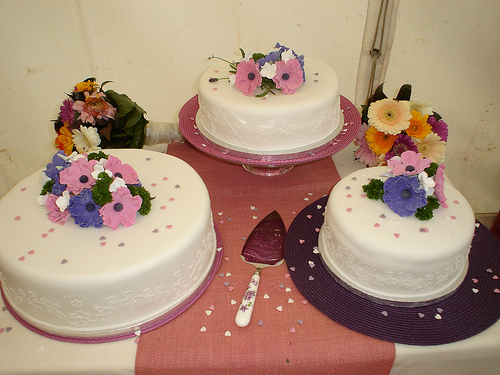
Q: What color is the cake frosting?
A: White.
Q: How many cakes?
A: Three.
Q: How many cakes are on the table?
A: Three.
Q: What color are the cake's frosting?
A: White.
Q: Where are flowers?
A: On the table.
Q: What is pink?
A: Two plates.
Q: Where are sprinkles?
A: On the cakes.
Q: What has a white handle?
A: Spatula.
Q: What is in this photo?
A: Cakes.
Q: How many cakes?
A: Three.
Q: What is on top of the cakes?
A: Icing.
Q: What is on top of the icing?
A: Flowers.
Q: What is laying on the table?
A: Knife to cut cake.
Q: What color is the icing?
A: White.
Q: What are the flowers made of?
A: Icing.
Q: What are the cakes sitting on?
A: A table.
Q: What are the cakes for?
A: Birthday.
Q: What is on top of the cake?
A: Many little flowers.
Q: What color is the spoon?
A: Silver and white.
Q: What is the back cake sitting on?
A: A cake stand.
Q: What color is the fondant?
A: White.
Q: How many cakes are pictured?
A: 3.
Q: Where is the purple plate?
A: Right.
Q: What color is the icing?
A: White.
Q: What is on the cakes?
A: Flowers.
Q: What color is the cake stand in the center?
A: Pink.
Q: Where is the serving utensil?
A: Center of the table.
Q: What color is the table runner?
A: Pink.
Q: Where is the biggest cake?
A: To the left.